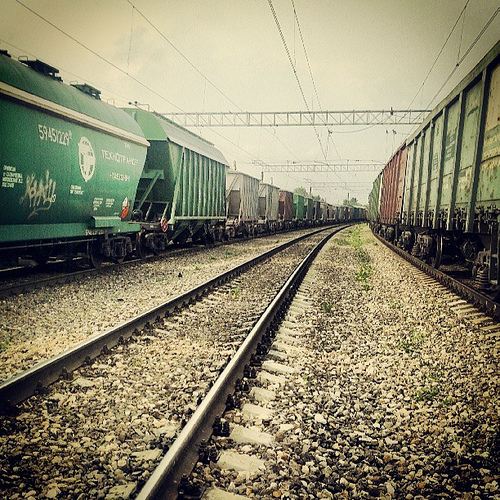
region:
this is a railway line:
[101, 277, 226, 428]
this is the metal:
[203, 360, 226, 413]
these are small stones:
[327, 374, 384, 437]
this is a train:
[50, 81, 127, 188]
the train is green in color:
[22, 125, 57, 192]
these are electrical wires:
[281, 33, 319, 70]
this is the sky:
[193, 17, 266, 77]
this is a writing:
[33, 122, 57, 134]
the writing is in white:
[40, 122, 69, 149]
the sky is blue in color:
[331, 22, 393, 94]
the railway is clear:
[129, 262, 316, 403]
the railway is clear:
[168, 270, 248, 416]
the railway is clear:
[157, 202, 332, 477]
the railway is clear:
[111, 217, 258, 393]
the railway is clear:
[182, 331, 289, 472]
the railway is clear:
[78, 173, 293, 463]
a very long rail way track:
[99, 199, 355, 464]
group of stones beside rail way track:
[317, 246, 462, 497]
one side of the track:
[168, 262, 333, 495]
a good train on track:
[55, 130, 332, 230]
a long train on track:
[344, 97, 496, 238]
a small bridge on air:
[205, 97, 423, 137]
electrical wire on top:
[246, 5, 365, 197]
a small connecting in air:
[383, 105, 398, 138]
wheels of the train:
[86, 233, 210, 252]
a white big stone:
[206, 440, 251, 483]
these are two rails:
[146, 249, 312, 380]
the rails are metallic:
[133, 280, 303, 388]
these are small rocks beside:
[328, 371, 416, 468]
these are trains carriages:
[5, 134, 186, 258]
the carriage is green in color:
[23, 99, 113, 195]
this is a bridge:
[346, 101, 373, 128]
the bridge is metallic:
[363, 102, 395, 126]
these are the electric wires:
[275, 48, 317, 83]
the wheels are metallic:
[418, 233, 475, 267]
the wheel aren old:
[437, 234, 485, 267]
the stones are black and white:
[375, 451, 389, 493]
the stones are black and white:
[366, 414, 381, 466]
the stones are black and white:
[364, 423, 376, 455]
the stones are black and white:
[369, 405, 383, 455]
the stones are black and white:
[357, 422, 380, 477]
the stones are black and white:
[346, 399, 367, 459]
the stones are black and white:
[376, 382, 393, 442]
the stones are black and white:
[395, 391, 412, 461]